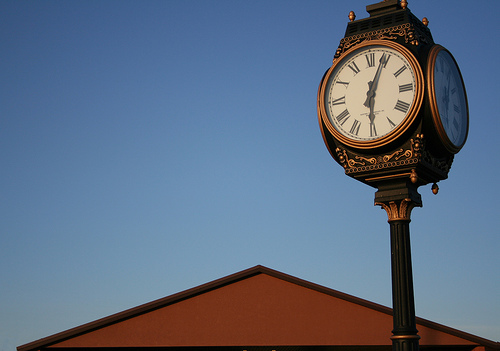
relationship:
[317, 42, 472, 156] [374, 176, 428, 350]
clocks on pole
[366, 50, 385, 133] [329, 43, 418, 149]
hands on clock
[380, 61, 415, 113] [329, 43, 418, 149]
numerals on clock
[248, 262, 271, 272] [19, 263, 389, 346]
peak on roof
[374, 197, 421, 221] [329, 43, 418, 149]
decotation under clock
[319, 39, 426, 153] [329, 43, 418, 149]
border around clockface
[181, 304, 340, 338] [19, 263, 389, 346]
wall under roof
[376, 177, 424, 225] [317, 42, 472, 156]
pedestal under clocks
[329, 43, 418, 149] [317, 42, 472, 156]
clock has faces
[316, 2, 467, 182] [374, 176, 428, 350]
clock on pole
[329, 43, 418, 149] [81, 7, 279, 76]
clock in sky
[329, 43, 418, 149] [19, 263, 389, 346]
clock above roof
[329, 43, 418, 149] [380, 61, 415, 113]
clock has numerals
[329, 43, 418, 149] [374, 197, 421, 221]
clock has ornament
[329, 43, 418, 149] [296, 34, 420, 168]
clock facing sun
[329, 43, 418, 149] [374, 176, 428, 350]
clock has pole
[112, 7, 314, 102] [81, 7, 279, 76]
portion of sky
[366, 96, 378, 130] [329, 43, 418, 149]
hand on clock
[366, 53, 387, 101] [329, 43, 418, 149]
hand on clock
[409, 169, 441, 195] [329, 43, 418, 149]
pieces on clock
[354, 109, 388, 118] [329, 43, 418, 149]
letters on clock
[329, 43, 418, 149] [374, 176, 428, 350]
clock on pole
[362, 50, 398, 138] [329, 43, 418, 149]
time on clock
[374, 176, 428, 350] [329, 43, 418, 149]
pole for clock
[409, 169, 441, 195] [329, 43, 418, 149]
decorations under clock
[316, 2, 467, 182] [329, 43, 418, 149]
four faced clock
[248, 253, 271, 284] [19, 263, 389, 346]
peak of roof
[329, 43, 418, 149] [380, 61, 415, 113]
clock with numerals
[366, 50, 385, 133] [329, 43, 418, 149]
hands of clock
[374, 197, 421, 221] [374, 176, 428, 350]
detail on pole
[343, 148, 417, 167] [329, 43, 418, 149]
scroll on clock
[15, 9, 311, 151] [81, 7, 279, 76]
clear blue sky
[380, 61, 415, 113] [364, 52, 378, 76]
roman numeral 12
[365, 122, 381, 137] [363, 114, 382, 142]
roman numeral 6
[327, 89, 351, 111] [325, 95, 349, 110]
roman numeral 9